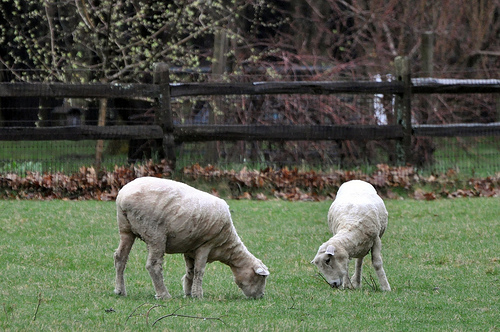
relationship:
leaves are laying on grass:
[1, 163, 500, 203] [1, 137, 500, 330]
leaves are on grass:
[1, 163, 500, 203] [1, 137, 500, 330]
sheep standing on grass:
[113, 176, 273, 302] [1, 137, 500, 330]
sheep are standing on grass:
[113, 176, 273, 302] [1, 137, 500, 330]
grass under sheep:
[1, 137, 500, 330] [113, 176, 273, 302]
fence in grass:
[2, 60, 500, 184] [1, 137, 500, 330]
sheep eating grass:
[113, 176, 273, 302] [1, 137, 500, 330]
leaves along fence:
[1, 163, 500, 203] [2, 60, 500, 184]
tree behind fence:
[1, 0, 257, 162] [2, 60, 500, 184]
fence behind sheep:
[2, 60, 500, 184] [113, 176, 273, 302]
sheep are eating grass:
[113, 176, 273, 302] [1, 137, 500, 330]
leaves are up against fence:
[1, 163, 500, 203] [2, 60, 500, 184]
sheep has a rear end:
[107, 179, 269, 306] [112, 180, 149, 232]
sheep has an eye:
[314, 178, 397, 292] [324, 256, 332, 264]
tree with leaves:
[1, 0, 257, 162] [7, 2, 257, 107]